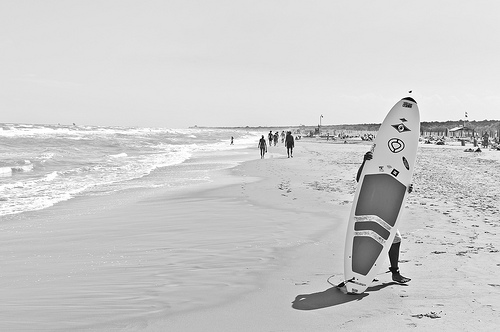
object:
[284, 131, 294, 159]
people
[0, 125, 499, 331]
beach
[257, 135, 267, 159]
people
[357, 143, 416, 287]
person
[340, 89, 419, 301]
surfboard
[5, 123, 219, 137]
waves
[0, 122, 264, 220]
ocean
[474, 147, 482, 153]
people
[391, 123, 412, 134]
markings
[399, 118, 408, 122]
markings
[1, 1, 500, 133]
sky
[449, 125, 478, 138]
building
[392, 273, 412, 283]
foot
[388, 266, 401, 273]
bracelet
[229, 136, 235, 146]
child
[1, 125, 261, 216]
shoreline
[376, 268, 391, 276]
leash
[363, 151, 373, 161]
hand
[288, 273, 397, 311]
shadow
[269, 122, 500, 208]
area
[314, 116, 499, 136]
hills